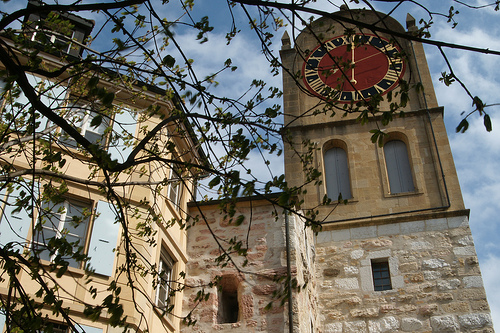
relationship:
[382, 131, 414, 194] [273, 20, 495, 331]
arched window on clock tower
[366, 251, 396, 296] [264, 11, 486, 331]
small window on clocktower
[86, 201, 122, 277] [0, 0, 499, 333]
window shutter on building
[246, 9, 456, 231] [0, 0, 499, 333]
clock on building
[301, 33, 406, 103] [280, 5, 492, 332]
clock on building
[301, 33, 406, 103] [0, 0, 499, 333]
clock on building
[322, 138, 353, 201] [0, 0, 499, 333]
arched window on building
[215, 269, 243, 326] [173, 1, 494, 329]
window on building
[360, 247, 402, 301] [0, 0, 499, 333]
window on building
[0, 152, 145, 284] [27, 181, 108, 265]
shutter on window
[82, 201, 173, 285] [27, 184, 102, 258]
shutter on window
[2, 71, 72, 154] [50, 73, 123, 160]
shutter on window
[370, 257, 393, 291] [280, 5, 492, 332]
window on building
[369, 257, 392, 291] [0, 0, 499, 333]
small window on building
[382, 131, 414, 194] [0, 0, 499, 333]
arched window on building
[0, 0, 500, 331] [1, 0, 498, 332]
cloud in sky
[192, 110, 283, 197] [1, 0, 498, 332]
cloud in sky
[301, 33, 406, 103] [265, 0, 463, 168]
clock on wall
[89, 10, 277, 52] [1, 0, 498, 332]
streak in sky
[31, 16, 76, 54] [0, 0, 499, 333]
window on top of building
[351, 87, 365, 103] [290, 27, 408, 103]
roman numeral on clock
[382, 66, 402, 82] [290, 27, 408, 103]
roman numeral on clock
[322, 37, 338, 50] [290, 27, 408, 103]
roman numeral on clock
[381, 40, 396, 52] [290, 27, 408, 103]
roman numeral on clock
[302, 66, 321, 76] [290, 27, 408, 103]
roman numeral on clock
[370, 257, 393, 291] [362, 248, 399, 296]
window inside frame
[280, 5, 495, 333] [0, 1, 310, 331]
clock tower connected to building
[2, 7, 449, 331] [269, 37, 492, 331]
outside on building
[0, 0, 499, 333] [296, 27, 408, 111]
building with clock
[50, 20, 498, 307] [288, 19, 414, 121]
building with clock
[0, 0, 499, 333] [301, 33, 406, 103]
building with clock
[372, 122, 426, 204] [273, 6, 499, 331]
arched window on tower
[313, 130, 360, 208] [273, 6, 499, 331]
arched window on tower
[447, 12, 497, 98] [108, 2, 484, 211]
sky with clouds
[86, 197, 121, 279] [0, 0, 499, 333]
window shutter on building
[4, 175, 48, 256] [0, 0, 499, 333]
window shutter on building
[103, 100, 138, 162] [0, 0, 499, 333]
window shutter on building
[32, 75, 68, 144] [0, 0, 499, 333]
window shutter on building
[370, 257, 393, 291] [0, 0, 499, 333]
window on building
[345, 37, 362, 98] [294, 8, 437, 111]
hand on clock